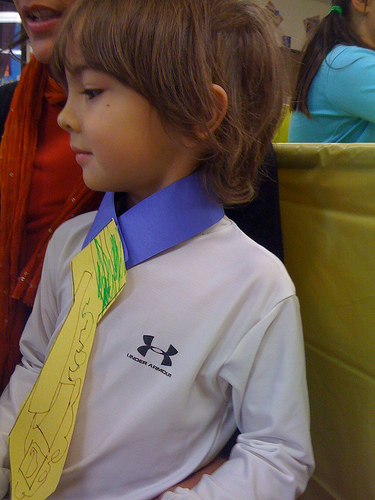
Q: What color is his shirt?
A: White.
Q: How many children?
A: One.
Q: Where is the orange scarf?
A: Woman's neck.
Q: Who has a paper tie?
A: The boy.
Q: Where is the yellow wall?
A: Behind them.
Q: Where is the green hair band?
A: Upper right quadrant.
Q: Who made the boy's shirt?
A: Under Armour.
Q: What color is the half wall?
A: Yellow.